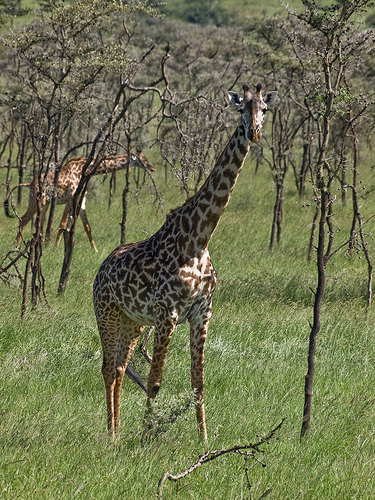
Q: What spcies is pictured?
A: Giraffe.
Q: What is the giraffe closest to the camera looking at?
A: The camera.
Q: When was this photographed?
A: Daytime.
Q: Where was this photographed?
A: Africa.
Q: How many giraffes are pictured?
A: Two.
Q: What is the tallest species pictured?
A: Tree.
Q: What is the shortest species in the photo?
A: Grass.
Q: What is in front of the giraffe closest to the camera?
A: A branch.